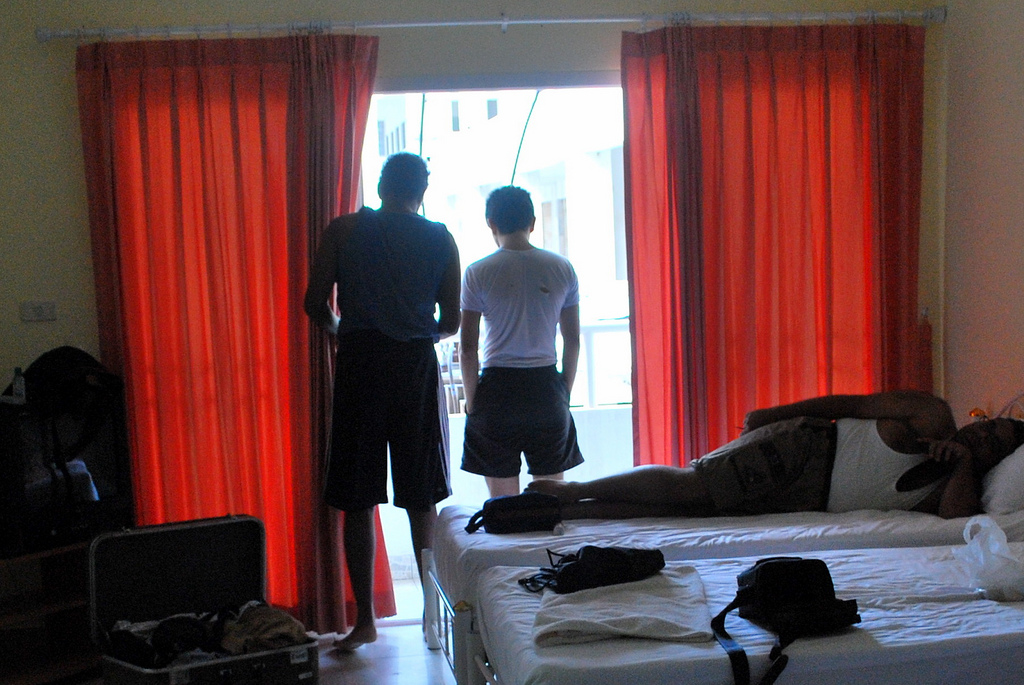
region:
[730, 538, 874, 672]
bag is on the bed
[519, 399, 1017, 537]
man is laying on the bed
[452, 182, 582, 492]
man is looking outside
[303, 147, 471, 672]
man is looking outside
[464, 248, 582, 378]
man has a white shirt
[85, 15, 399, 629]
curtain is red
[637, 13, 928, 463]
curtain is red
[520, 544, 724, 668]
towel is on the bed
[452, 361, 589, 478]
man is wearing shorts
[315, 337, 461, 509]
man is wearing shorts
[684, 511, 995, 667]
A black bag is on the bed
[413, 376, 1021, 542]
A person is laying on the bed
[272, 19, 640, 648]
People looking out the window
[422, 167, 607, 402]
The person is wearing a white shirt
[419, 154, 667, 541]
The person is wearing shorts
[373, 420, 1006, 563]
The bed has white sheets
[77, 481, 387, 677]
The open suitcase is on the ground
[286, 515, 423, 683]
The foot is bare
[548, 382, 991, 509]
The person lying on the bed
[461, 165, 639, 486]
The short man standing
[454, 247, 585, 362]
The white shirt on the short man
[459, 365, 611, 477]
The short black pants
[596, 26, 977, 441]
The red curtain to the right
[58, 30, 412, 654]
The red curtain to the right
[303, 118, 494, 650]
The tall man standing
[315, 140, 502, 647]
A tall man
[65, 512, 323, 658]
The suitcase with clothes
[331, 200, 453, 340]
man wearing a gray shirt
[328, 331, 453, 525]
man wearing black shorts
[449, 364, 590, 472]
man wearing black shorts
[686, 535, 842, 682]
black bag on the bed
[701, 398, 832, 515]
man wearing brown shorts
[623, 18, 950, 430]
red curtain on the window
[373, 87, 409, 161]
glass window on the bilding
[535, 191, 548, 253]
glass window on the bilding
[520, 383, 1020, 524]
a man laying down in a bed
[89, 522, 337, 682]
a open suitcase on the floor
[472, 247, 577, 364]
a young man wearing a white shirt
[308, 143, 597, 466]
two young men standing in a glass door way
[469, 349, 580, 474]
a young man wearing black shorts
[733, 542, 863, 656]
a black bag on a bed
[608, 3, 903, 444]
a red curtain covering a doorway and window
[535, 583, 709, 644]
a white towel on a bed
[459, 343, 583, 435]
a young man with his hands in his pockets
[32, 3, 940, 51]
a long white curtain rod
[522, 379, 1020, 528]
a man laying on a bed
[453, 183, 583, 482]
a man with his hands in his pockets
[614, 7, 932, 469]
a red curtain hanging on a curtain rod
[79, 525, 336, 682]
a suitcase on the floor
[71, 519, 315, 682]
a open suitcase on the floor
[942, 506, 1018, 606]
a white plastic bag on a bed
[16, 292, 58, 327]
a white electrical switch on a wall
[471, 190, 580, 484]
A person is standing up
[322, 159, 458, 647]
A person is standing up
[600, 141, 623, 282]
A window on a building.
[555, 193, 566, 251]
A window on a building.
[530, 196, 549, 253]
A window on a building.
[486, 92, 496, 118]
A window on a building.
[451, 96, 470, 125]
A window on a building.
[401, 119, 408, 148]
A window on a building.